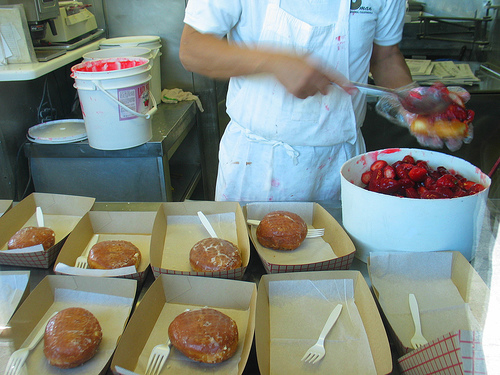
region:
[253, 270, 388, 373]
food tray containing a plastic fork and white paper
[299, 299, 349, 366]
plastic fork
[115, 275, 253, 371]
brown food tray containing a donut and a fork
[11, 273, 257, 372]
two brown trays each containing a donut and a fork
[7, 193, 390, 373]
brown food trays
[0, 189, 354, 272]
four brown food trays each containing a donut and fork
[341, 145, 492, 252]
white bucket of strawberries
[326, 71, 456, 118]
large silver spoon covered with strawberries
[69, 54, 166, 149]
white pail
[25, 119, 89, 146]
white bucket lid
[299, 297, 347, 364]
a white plastic fork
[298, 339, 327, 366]
the tines of a fork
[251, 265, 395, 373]
a brown cardboard tray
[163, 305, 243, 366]
a brown pastry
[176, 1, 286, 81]
the arm of a person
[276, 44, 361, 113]
the hand of a person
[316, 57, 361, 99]
the finger of a person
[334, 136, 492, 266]
a white bucket filled with strawberries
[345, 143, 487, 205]
red strawberries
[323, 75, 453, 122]
a metal spoon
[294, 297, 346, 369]
WHITE PLASTIC FORK IN EMPTY BOX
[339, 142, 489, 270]
BUCKET FULL OF STRAWBERRIES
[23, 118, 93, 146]
WHITE BUCKET LID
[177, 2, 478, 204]
MAN MAKING STRAWBERRY DONUTS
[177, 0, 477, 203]
MAN WEARING PLASTIC GLOVE ON RIGHT HAND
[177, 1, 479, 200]
MAN HOLDING SILVER SPOON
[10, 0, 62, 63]
COFFEE MAKER IN THE BACKGROUND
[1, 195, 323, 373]
SIX DONUTS READY TO EAT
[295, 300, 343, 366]
WHITE SPOON WITH 4 PRONGS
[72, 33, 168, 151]
THREE WHITE BUCKETS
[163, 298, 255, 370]
glazed donut in box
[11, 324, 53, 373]
white plastic fork faced down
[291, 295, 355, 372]
white fork on paper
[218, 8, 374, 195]
white apron on man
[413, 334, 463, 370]
red design on box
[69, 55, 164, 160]
white bucket with handle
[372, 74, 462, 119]
metal spoon placing strawberries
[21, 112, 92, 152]
cover of plastic bucket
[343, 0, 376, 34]
emblem on shirt chest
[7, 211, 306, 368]
The donuts in cardboard serving dishes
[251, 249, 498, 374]
The three empty cardboard serving dishes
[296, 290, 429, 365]
The forks in the empty dishes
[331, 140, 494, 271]
The white tub with strawberries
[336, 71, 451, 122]
The large serving spoon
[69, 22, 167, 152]
The three white buckets in a line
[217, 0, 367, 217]
The man's apron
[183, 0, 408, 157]
The man's white shirt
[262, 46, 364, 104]
The hand holding the spoon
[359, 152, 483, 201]
The strawberries in the tub